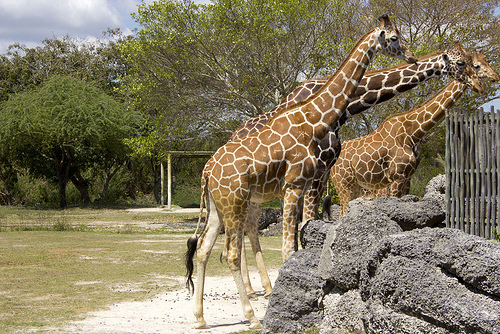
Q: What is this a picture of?
A: Giraffes.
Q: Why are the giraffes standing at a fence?
A: They are looking over the fence.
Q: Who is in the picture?
A: Giraffes.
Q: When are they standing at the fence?
A: During the day.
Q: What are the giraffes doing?
A: Looking over the fence.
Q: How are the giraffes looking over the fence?
A: In a standing position.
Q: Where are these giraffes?
A: A zoo.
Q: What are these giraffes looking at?
A: Possibly someone on the other side of the fence.